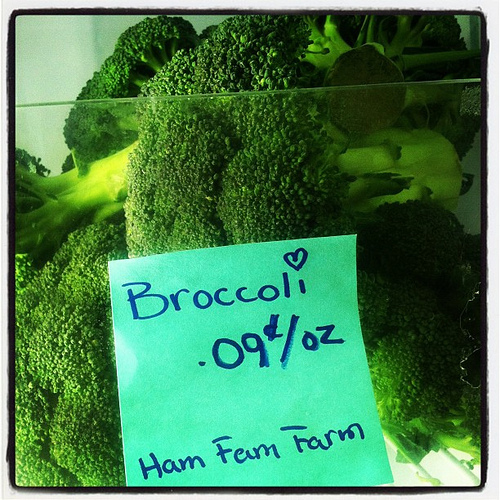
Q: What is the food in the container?
A: Broccoli.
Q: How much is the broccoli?
A: .09 and ounce.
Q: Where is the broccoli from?
A: Ham Fam Farm.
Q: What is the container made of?
A: Plastic.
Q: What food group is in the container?
A: Vegetables.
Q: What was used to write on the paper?
A: A marker.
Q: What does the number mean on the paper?
A: The price.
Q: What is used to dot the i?
A: A heart.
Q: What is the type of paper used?
A: A stickynote.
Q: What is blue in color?
A: The paper.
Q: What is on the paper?
A: Writing.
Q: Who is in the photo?
A: No people.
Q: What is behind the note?
A: Food.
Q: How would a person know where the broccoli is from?
A: Sign.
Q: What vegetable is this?
A: Broccoli.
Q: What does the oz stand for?
A: Ounce.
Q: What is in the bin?
A: Broccoli.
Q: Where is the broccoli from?
A: Ham Fam Farm.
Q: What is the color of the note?
A: Green.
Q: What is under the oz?
A: Name of the farm.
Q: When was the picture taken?
A: During the day.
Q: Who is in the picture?
A: No one.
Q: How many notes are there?
A: 1.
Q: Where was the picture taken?
A: Grocery store.